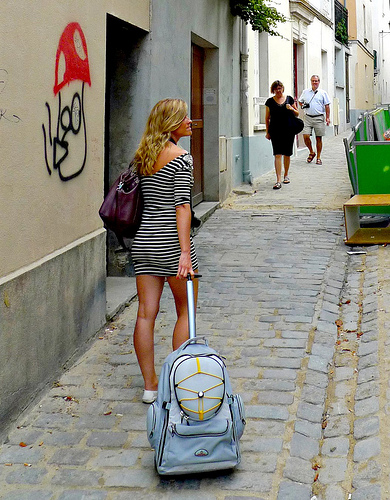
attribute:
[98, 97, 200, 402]
woman — young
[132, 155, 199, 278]
dress — striped, short, white, black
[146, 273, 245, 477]
luggage — blue, rolling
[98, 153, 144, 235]
purse — purple, leather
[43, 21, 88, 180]
graffiti — painted, red, black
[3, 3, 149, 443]
wall — stone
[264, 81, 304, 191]
woman — dressed, older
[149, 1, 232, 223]
building — cement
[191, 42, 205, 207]
entrance — shiny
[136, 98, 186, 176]
hair — blonde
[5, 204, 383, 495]
sidewalk — cobblestone, grey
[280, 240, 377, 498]
gutter — cobblestone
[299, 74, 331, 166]
pedestrian — older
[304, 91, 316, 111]
camera — carried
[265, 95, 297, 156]
dress — black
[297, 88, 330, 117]
shirt — blue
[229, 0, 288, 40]
leaves — green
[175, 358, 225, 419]
cording — yellow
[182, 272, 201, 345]
handle — metal